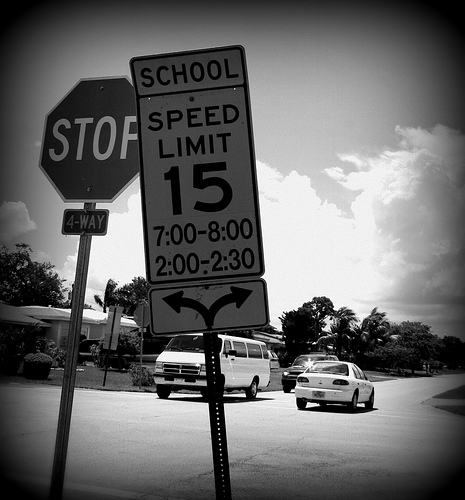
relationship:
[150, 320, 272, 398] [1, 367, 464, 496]
van at an intersection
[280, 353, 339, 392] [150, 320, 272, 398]
truck behind a van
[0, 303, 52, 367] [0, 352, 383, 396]
house on corner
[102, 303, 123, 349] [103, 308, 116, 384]
sign on pole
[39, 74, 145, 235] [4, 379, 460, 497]
stop sign at intersection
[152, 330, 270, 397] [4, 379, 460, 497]
van at intersection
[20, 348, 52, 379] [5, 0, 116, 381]
bush on corner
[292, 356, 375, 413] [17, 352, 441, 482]
white car on road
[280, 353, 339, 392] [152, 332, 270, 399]
truck behind van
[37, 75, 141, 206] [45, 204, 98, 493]
sign on pole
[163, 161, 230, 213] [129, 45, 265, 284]
15 on sign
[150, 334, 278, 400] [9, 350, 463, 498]
van on road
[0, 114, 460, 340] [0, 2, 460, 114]
clouds in sky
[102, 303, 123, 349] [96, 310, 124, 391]
sign on post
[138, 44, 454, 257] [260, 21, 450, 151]
sky has part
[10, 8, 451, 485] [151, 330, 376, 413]
photo has cars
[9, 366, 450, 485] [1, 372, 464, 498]
tarmac has road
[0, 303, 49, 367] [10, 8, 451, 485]
house in photo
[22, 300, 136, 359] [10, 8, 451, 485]
house in photo